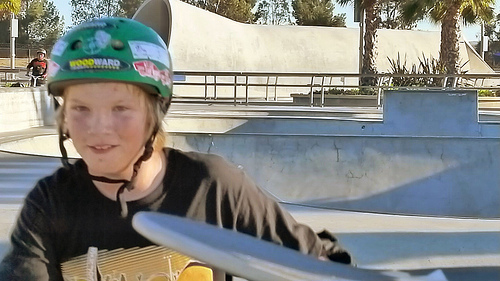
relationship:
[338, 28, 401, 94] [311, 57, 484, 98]
tree trunk in foliage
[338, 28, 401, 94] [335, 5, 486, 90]
tree trunk in foliage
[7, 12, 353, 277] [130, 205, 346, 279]
boy at skatepark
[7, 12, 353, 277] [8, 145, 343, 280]
boy wearing shirt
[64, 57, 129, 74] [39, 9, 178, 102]
sticker holding helmet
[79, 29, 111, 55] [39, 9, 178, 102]
sticker holding helmet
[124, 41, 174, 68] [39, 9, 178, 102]
sticker holding helmet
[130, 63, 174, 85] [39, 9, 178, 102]
sticker holding helmet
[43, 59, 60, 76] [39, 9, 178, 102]
sticker holding helmet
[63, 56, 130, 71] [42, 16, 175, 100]
logo on helmet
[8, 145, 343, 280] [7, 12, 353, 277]
shirt of boy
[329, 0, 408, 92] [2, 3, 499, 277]
tree in park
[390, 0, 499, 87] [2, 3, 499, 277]
tree in park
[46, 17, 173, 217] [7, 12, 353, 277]
helmet on boy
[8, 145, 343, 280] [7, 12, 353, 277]
shirt on boy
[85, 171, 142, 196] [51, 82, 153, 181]
strap under face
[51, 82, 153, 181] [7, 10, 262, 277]
face of boy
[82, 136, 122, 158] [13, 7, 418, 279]
smile on boy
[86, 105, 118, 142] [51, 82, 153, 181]
nose on face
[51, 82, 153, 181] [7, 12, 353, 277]
face on boy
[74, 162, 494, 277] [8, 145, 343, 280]
design on shirt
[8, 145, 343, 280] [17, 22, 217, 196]
shirt on boy's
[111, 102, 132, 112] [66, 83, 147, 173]
eye on face